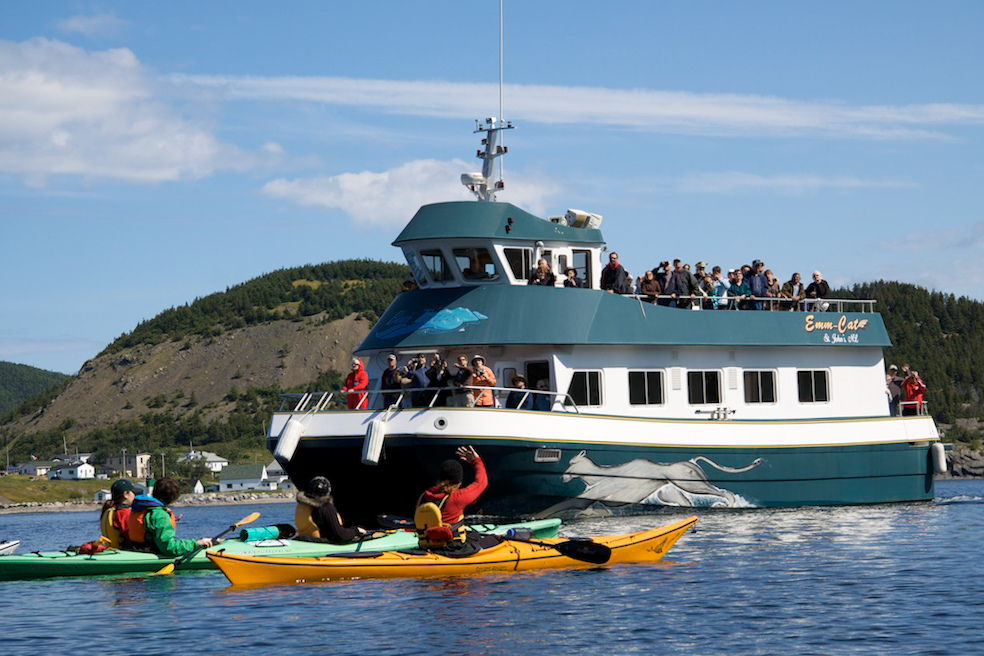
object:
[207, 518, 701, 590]
kayak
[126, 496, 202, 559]
jacket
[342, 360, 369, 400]
coat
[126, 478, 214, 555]
woman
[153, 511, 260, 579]
oar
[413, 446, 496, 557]
man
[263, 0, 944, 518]
ship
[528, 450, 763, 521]
animal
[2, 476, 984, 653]
water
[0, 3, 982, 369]
sky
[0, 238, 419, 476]
hill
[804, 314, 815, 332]
letter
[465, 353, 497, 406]
person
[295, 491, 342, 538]
lifejacket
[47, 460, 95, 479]
house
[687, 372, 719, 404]
window